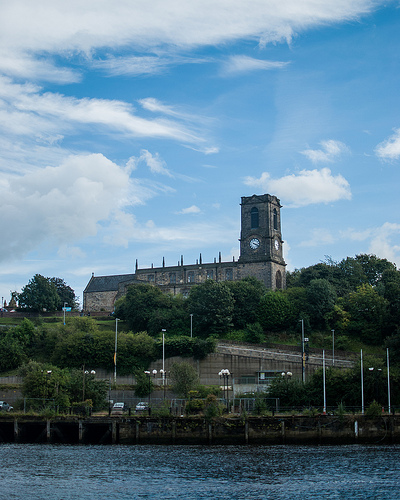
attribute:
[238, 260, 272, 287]
walls — brick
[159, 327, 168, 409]
post — lamp post, tall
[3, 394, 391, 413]
lot — parking lot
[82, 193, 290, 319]
building — stone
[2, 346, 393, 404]
wall — stone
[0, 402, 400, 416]
area — parking area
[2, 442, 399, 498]
water — river water, calmly flowing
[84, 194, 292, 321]
structure — stone, old, large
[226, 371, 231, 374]
globe — white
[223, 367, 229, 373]
globe — white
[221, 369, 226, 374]
globe — white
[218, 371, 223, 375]
globe — white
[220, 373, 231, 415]
post — lamp post